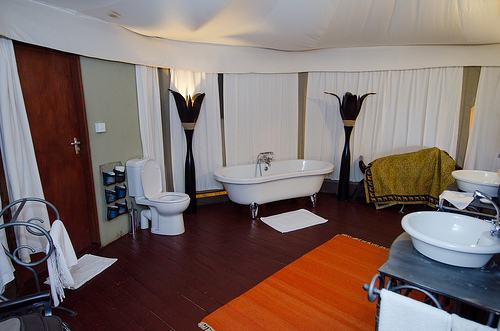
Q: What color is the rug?
A: Orange.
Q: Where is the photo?
A: Bathroom.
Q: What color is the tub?
A: White.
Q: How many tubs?
A: One.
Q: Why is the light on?
A: To provide light.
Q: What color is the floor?
A: Brown.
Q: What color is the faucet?
A: Silver.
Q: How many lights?
A: One.